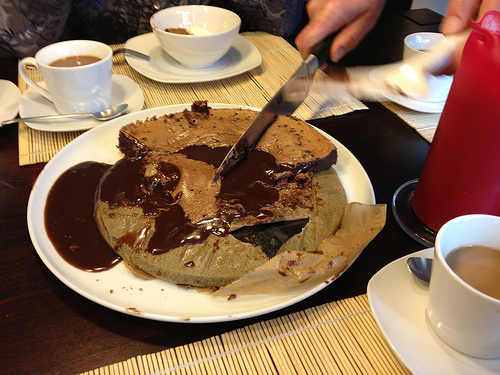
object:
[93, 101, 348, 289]
cake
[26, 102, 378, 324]
plate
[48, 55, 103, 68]
coffe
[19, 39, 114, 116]
cup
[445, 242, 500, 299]
coffe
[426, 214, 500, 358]
cup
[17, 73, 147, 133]
saucer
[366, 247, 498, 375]
saucer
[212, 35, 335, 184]
knife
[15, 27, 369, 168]
placemat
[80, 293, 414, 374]
placemat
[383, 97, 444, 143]
placemat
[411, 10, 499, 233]
candle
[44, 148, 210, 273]
chocolate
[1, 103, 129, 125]
spoon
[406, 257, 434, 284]
spoon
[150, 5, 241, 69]
bowl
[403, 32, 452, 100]
cup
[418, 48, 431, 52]
coffee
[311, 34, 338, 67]
handle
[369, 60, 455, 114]
saucer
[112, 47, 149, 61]
fork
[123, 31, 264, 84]
saucer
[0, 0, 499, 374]
table